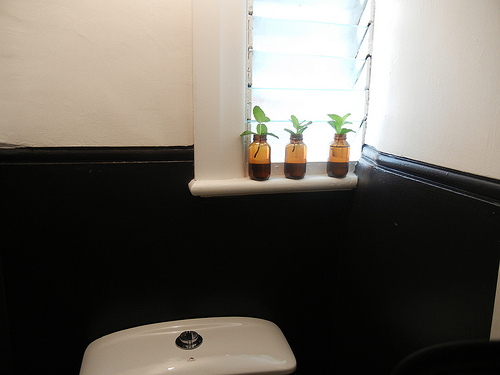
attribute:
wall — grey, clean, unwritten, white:
[1, 1, 500, 180]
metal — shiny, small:
[177, 327, 203, 351]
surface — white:
[78, 312, 298, 373]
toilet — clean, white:
[76, 315, 296, 375]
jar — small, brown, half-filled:
[245, 132, 273, 184]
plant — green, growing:
[239, 104, 282, 139]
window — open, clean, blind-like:
[248, 0, 361, 165]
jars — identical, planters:
[245, 134, 352, 179]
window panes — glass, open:
[251, 3, 362, 160]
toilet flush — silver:
[176, 329, 202, 351]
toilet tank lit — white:
[81, 312, 296, 373]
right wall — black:
[360, 149, 499, 374]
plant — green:
[286, 113, 316, 135]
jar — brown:
[283, 133, 309, 180]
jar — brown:
[327, 135, 350, 179]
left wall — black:
[1, 146, 364, 374]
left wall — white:
[2, 0, 194, 146]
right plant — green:
[327, 110, 357, 140]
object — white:
[488, 248, 499, 341]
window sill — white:
[187, 179, 366, 198]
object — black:
[382, 338, 498, 373]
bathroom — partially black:
[1, 2, 500, 374]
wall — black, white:
[0, 0, 364, 375]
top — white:
[75, 313, 294, 374]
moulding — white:
[193, 0, 246, 180]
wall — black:
[0, 162, 499, 373]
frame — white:
[193, 0, 242, 179]